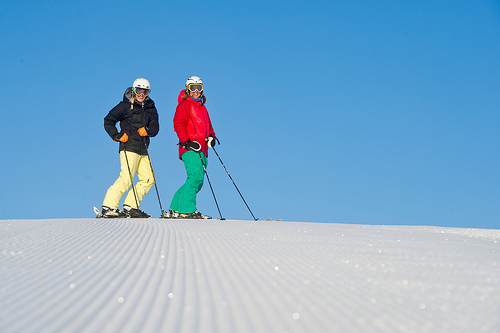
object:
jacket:
[173, 90, 217, 161]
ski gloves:
[180, 140, 201, 151]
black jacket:
[104, 87, 160, 156]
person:
[170, 76, 218, 214]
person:
[102, 78, 159, 209]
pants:
[103, 150, 152, 210]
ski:
[156, 210, 218, 220]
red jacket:
[172, 89, 217, 161]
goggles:
[132, 87, 152, 97]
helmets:
[132, 77, 153, 92]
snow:
[1, 217, 499, 331]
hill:
[0, 220, 498, 332]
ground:
[0, 216, 499, 330]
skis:
[93, 203, 154, 219]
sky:
[0, 0, 500, 230]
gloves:
[115, 132, 128, 143]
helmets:
[186, 75, 203, 89]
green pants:
[170, 149, 204, 215]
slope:
[0, 218, 500, 333]